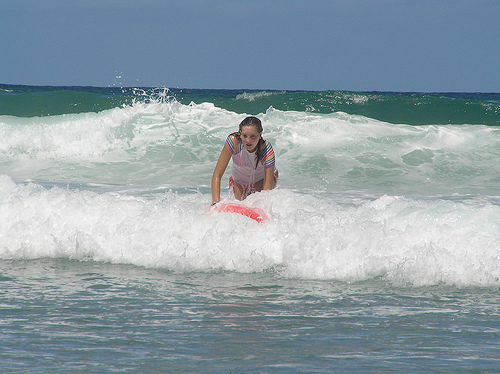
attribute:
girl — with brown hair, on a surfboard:
[206, 110, 286, 234]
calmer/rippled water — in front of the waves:
[35, 273, 233, 371]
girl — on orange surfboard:
[206, 112, 285, 224]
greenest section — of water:
[11, 87, 95, 112]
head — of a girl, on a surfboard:
[235, 114, 265, 149]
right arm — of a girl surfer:
[211, 132, 232, 202]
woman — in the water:
[207, 113, 281, 224]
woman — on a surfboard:
[208, 113, 287, 226]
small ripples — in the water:
[103, 323, 299, 372]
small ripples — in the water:
[225, 302, 398, 372]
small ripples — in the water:
[32, 303, 165, 371]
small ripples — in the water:
[137, 274, 244, 314]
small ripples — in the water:
[246, 326, 300, 364]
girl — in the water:
[211, 116, 281, 226]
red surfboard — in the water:
[206, 197, 271, 224]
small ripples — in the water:
[36, 279, 266, 365]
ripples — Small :
[178, 283, 203, 308]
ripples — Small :
[69, 217, 189, 343]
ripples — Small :
[165, 267, 217, 306]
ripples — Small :
[113, 242, 226, 335]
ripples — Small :
[130, 250, 208, 329]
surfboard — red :
[175, 168, 282, 238]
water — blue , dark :
[32, 46, 466, 369]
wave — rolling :
[37, 70, 472, 308]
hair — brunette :
[239, 101, 293, 143]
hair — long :
[245, 101, 275, 181]